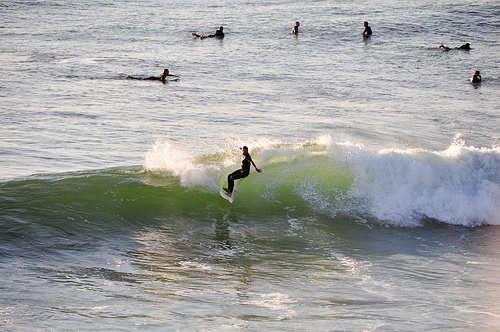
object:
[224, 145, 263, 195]
man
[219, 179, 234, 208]
surfboard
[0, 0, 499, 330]
water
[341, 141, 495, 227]
wave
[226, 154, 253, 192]
wetsuit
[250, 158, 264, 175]
arms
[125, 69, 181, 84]
person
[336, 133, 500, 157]
crest